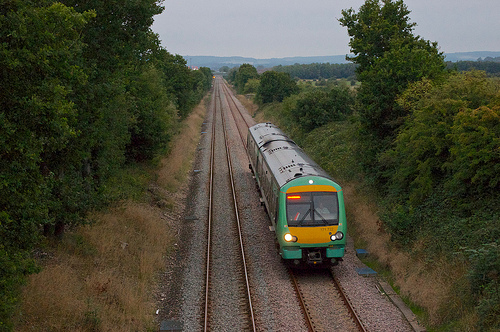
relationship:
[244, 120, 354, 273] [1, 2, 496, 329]
train between bushes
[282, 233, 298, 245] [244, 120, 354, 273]
headlight of train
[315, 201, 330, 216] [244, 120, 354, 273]
person driving train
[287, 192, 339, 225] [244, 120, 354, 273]
windshield of train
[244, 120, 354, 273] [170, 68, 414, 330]
train driving on rail road tracks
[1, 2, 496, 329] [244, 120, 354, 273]
bushes near train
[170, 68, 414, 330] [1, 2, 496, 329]
rail road tracks near bushes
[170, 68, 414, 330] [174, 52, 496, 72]
rail road tracks running through mountains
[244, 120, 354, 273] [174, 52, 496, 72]
train coming around mountains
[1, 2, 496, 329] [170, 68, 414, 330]
bushes near rail road tracks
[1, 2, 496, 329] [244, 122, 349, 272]
bushes near train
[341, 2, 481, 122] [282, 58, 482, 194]
tree on hillside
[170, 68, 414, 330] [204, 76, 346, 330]
rail road tracks with lanes